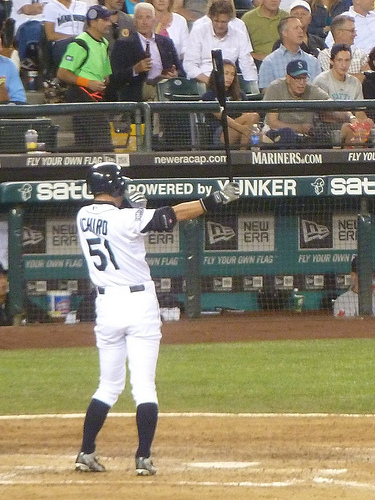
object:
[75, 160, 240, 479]
player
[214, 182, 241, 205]
glove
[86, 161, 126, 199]
helmet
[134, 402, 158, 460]
sock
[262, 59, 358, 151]
man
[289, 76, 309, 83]
glasses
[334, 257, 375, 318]
person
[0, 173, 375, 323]
dugout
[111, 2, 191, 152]
man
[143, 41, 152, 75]
beer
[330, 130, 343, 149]
cup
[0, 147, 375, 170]
ledge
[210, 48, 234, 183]
bat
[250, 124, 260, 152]
bottle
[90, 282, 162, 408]
pants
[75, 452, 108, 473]
shoe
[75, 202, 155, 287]
shirt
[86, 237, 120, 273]
number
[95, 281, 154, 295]
belt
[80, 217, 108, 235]
name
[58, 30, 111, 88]
shirt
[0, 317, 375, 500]
field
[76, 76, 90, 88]
armband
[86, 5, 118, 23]
cap